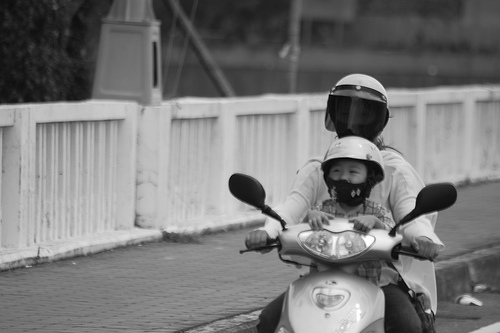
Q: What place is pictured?
A: It is a sidewalk.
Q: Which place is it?
A: It is a sidewalk.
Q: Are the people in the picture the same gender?
A: No, they are both male and female.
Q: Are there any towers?
A: No, there are no towers.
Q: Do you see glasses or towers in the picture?
A: No, there are no towers or glasses.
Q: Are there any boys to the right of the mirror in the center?
A: Yes, there is a boy to the right of the mirror.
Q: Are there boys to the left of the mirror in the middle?
A: No, the boy is to the right of the mirror.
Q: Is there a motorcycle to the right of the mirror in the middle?
A: No, there is a boy to the right of the mirror.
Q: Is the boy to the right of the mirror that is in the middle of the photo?
A: Yes, the boy is to the right of the mirror.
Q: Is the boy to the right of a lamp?
A: No, the boy is to the right of the mirror.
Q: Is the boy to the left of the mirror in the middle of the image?
A: No, the boy is to the right of the mirror.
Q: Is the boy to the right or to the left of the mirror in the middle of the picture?
A: The boy is to the right of the mirror.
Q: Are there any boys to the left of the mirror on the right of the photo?
A: Yes, there is a boy to the left of the mirror.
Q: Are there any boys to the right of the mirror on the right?
A: No, the boy is to the left of the mirror.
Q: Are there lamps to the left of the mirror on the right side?
A: No, there is a boy to the left of the mirror.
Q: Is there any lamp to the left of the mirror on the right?
A: No, there is a boy to the left of the mirror.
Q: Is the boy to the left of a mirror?
A: Yes, the boy is to the left of a mirror.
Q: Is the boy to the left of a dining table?
A: No, the boy is to the left of a mirror.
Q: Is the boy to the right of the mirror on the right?
A: No, the boy is to the left of the mirror.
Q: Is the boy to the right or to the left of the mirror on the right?
A: The boy is to the left of the mirror.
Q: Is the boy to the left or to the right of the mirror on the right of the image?
A: The boy is to the left of the mirror.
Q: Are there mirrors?
A: Yes, there is a mirror.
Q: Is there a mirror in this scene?
A: Yes, there is a mirror.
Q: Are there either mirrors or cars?
A: Yes, there is a mirror.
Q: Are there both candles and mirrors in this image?
A: No, there is a mirror but no candles.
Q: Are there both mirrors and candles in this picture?
A: No, there is a mirror but no candles.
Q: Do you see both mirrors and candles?
A: No, there is a mirror but no candles.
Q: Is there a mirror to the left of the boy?
A: Yes, there is a mirror to the left of the boy.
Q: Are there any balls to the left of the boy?
A: No, there is a mirror to the left of the boy.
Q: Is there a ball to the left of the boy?
A: No, there is a mirror to the left of the boy.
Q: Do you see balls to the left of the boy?
A: No, there is a mirror to the left of the boy.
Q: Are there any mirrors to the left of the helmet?
A: Yes, there is a mirror to the left of the helmet.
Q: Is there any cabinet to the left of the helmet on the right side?
A: No, there is a mirror to the left of the helmet.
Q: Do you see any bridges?
A: Yes, there is a bridge.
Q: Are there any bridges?
A: Yes, there is a bridge.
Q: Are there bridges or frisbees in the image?
A: Yes, there is a bridge.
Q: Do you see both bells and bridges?
A: No, there is a bridge but no bells.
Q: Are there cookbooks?
A: No, there are no cookbooks.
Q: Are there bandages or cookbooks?
A: No, there are no cookbooks or bandages.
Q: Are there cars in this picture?
A: No, there are no cars.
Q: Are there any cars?
A: No, there are no cars.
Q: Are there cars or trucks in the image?
A: No, there are no cars or trucks.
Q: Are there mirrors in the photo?
A: Yes, there is a mirror.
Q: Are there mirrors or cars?
A: Yes, there is a mirror.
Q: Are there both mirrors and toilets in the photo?
A: No, there is a mirror but no toilets.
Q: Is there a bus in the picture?
A: No, there are no buses.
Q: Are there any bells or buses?
A: No, there are no buses or bells.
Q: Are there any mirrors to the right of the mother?
A: Yes, there is a mirror to the right of the mother.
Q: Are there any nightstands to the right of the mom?
A: No, there is a mirror to the right of the mom.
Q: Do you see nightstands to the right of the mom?
A: No, there is a mirror to the right of the mom.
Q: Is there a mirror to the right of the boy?
A: Yes, there is a mirror to the right of the boy.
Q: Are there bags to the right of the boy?
A: No, there is a mirror to the right of the boy.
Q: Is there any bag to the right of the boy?
A: No, there is a mirror to the right of the boy.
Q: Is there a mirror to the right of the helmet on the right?
A: Yes, there is a mirror to the right of the helmet.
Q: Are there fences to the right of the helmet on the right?
A: No, there is a mirror to the right of the helmet.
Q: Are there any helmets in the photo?
A: Yes, there is a helmet.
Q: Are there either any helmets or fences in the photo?
A: Yes, there is a helmet.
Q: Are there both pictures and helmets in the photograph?
A: No, there is a helmet but no pictures.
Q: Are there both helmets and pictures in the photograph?
A: No, there is a helmet but no pictures.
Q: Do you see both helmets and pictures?
A: No, there is a helmet but no pictures.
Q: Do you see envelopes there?
A: No, there are no envelopes.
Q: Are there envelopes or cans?
A: No, there are no envelopes or cans.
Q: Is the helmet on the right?
A: Yes, the helmet is on the right of the image.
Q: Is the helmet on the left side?
A: No, the helmet is on the right of the image.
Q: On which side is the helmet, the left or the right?
A: The helmet is on the right of the image.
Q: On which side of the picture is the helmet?
A: The helmet is on the right of the image.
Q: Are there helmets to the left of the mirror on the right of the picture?
A: Yes, there is a helmet to the left of the mirror.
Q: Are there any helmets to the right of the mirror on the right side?
A: No, the helmet is to the left of the mirror.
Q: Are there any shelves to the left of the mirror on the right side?
A: No, there is a helmet to the left of the mirror.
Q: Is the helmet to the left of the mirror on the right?
A: Yes, the helmet is to the left of the mirror.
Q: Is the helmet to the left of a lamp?
A: No, the helmet is to the left of the mirror.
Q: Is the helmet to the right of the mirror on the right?
A: No, the helmet is to the left of the mirror.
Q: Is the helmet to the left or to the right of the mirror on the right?
A: The helmet is to the left of the mirror.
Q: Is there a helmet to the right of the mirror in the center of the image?
A: Yes, there is a helmet to the right of the mirror.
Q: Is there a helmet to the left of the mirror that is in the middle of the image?
A: No, the helmet is to the right of the mirror.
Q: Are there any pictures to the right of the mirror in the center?
A: No, there is a helmet to the right of the mirror.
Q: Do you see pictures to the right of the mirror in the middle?
A: No, there is a helmet to the right of the mirror.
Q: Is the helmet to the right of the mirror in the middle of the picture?
A: Yes, the helmet is to the right of the mirror.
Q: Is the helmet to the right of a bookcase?
A: No, the helmet is to the right of the mirror.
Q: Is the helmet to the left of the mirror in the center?
A: No, the helmet is to the right of the mirror.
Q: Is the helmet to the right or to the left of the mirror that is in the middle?
A: The helmet is to the right of the mirror.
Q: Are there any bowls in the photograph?
A: No, there are no bowls.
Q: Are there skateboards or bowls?
A: No, there are no bowls or skateboards.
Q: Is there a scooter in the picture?
A: Yes, there is a scooter.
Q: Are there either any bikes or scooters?
A: Yes, there is a scooter.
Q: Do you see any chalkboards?
A: No, there are no chalkboards.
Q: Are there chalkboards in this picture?
A: No, there are no chalkboards.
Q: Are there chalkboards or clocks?
A: No, there are no chalkboards or clocks.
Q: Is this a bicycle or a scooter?
A: This is a scooter.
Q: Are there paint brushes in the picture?
A: No, there are no paint brushes.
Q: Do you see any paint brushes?
A: No, there are no paint brushes.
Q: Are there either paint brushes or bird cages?
A: No, there are no paint brushes or bird cages.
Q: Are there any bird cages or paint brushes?
A: No, there are no paint brushes or bird cages.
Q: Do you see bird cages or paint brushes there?
A: No, there are no paint brushes or bird cages.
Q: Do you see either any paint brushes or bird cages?
A: No, there are no paint brushes or bird cages.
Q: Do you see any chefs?
A: No, there are no chefs.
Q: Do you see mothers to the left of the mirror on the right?
A: Yes, there is a mother to the left of the mirror.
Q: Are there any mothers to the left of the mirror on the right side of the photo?
A: Yes, there is a mother to the left of the mirror.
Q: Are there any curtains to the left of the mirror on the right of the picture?
A: No, there is a mother to the left of the mirror.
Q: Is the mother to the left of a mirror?
A: Yes, the mother is to the left of a mirror.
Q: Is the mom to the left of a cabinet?
A: No, the mom is to the left of a mirror.